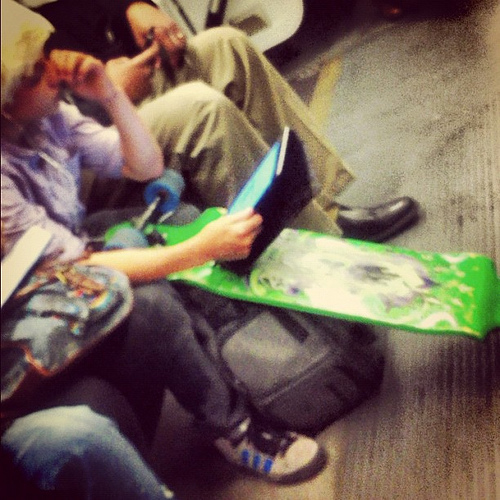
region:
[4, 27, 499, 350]
A kid sitting with skateboard and tablet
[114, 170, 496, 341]
Green skateboard with blue wheels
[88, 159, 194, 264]
Blue wheels of skateboard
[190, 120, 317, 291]
Hand holding a tablet on top of skateboard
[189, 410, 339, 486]
Right tennis shoe with 3 blue stripes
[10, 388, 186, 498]
Knee with jean pants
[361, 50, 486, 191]
Gray and brown colored floor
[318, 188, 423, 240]
Left brown loafer with yellow sock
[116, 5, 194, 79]
Left hand of man wearing ring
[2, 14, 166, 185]
Profile of kids face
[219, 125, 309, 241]
boy holds tablet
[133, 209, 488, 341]
boy holds green skateboard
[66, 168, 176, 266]
green skateboard has blue wheels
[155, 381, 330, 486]
boy wears white shoes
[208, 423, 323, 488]
white shoes have blue stripes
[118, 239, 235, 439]
boy wears black jeans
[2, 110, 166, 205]
boy wears white shirt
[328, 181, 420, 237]
man wears black shoes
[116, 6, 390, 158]
man wears khaki slacks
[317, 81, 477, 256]
floor of transport is grey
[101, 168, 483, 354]
The boy is holding a skateboard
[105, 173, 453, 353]
The skateboard is green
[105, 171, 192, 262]
The skateboard has blue wheels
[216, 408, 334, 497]
The person is wearing white and blue shoes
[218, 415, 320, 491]
The shoes have black laces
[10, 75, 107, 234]
The man is wearing white earphones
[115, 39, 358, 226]
The person is wearing beige pants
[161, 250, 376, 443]
The backpack is grey and black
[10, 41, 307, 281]
The man is looking at a tablet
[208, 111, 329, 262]
The tablet has a black cover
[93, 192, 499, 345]
the skateboard is green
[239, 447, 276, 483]
the shoes have blue stripes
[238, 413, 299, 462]
the shoelaces are black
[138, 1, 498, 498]
the floor is dirty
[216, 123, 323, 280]
the kid is holding an i-pad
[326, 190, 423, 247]
the man is wearing black shoes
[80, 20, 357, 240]
the man is wearing tan pants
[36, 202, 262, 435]
the kid is wearing jeans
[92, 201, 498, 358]
the wheels are on the skateboard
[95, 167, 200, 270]
the wheels are blue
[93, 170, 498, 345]
a bright green skateboard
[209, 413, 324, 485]
white athletic shoe with blue stripes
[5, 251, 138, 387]
colorful skateboard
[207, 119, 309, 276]
an open running iPad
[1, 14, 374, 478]
a boy sitting in a chair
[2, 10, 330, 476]
a boy using an iPad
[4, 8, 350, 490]
a boy using a tablet computer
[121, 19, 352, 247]
a pair of brown khaki pants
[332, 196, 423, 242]
a black leather shoe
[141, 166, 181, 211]
a blue skateboard wheel